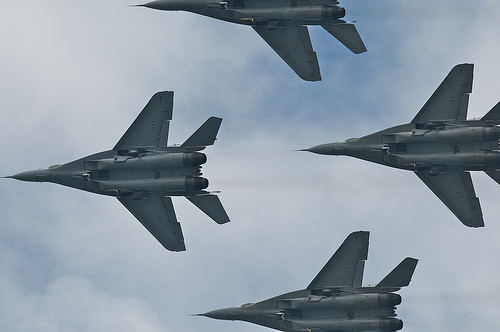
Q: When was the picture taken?
A: Daytime.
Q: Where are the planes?
A: In the air.